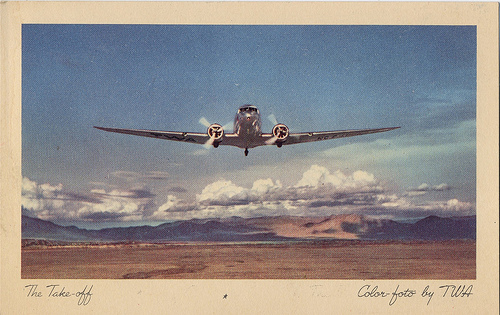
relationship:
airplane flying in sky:
[85, 100, 404, 157] [23, 22, 478, 229]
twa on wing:
[148, 130, 198, 143] [75, 116, 239, 161]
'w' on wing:
[167, 132, 180, 144] [154, 131, 199, 145]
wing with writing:
[260, 118, 402, 150] [303, 136, 361, 141]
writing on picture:
[23, 283, 473, 305] [21, 25, 475, 279]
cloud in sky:
[337, 172, 380, 205] [224, 41, 390, 111]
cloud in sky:
[286, 165, 346, 207] [224, 41, 390, 111]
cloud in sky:
[251, 171, 298, 208] [224, 41, 390, 111]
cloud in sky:
[197, 174, 267, 214] [224, 41, 390, 111]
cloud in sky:
[157, 179, 214, 228] [224, 41, 390, 111]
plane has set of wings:
[94, 104, 399, 159] [263, 125, 405, 147]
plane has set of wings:
[94, 104, 399, 159] [89, 124, 236, 146]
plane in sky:
[94, 104, 399, 159] [26, 26, 476, 214]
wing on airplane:
[90, 113, 229, 160] [85, 100, 404, 157]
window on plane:
[235, 105, 259, 115] [103, 97, 414, 180]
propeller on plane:
[262, 111, 301, 151] [94, 104, 399, 159]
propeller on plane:
[195, 115, 240, 150] [94, 104, 399, 159]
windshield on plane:
[239, 106, 256, 115] [83, 90, 416, 185]